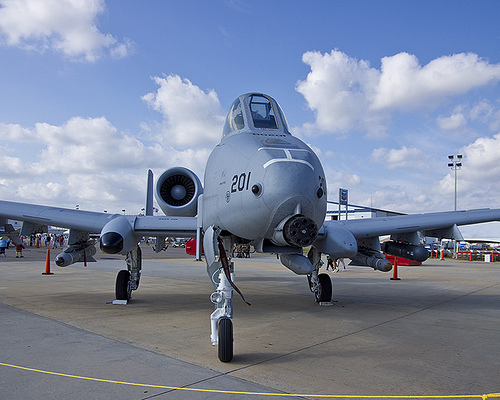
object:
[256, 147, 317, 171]
lines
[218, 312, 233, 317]
handle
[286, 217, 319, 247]
gun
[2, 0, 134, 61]
cloud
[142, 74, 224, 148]
cloud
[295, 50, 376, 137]
cloud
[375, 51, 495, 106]
cloud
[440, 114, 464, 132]
cloud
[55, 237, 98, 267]
missle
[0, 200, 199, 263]
wing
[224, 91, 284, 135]
cockpit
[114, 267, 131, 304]
tire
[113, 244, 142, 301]
landing gear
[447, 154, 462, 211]
pole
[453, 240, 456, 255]
pole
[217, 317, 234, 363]
tire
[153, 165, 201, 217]
engine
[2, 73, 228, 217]
clouds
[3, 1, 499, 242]
sky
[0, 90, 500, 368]
jet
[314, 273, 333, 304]
plane wheel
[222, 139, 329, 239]
nose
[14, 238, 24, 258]
people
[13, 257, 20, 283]
people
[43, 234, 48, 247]
people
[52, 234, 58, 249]
people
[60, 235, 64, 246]
people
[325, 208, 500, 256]
wing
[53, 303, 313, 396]
turmac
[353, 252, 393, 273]
missle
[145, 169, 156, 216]
tail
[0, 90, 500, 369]
foreground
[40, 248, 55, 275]
cones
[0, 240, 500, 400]
airport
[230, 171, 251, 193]
201